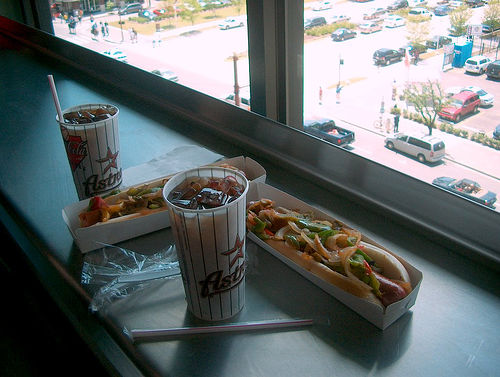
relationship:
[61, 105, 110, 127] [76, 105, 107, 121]
soda with ice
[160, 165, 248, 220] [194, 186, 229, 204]
soda with ice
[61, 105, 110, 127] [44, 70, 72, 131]
soda with straw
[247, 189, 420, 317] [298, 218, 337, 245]
hot dog with peppers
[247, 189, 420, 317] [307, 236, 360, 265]
hot dog with onions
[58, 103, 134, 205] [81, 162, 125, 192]
cup with logo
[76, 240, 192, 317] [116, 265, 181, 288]
plastic for utensil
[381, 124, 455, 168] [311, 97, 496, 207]
van on street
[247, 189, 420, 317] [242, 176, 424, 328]
hot dog in holder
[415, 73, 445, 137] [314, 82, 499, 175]
tree on sidewalk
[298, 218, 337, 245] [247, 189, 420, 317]
peppers on hot dog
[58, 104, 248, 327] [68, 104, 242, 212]
cups with soda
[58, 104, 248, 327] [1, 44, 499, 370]
cups on counter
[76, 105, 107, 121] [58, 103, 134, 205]
ice in cup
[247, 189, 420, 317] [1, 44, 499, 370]
hot dog on counter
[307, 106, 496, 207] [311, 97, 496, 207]
cars on street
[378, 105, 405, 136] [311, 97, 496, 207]
people on street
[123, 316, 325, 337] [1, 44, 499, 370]
straw on counter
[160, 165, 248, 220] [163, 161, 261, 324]
soda in cup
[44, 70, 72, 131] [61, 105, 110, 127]
straw in soda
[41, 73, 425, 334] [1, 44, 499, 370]
snacks on counter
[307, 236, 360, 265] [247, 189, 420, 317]
onions on hot dog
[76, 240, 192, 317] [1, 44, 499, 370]
plastic on counter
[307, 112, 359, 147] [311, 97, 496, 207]
truck on street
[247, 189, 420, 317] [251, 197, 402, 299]
hot dog in bun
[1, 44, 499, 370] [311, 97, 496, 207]
counter above street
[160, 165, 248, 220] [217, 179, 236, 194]
soda with ice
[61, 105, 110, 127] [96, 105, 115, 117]
soda with ice